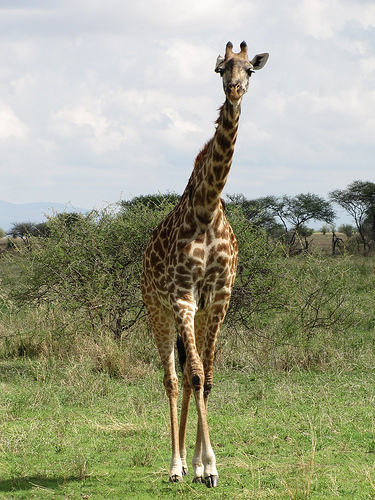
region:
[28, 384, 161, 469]
Tall grass beneath the giraffe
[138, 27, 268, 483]
A very tall giraffe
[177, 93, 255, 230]
The giraffe's neck is long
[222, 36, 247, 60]
The giraffe's antlers are small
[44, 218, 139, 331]
Small trees behind the giraffe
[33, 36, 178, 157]
Thick white clouds in the sky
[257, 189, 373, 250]
Sparse trees in the distance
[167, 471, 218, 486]
A set of black hooves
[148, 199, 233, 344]
The giraffe has many spots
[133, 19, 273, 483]
A yellow and brown giraffe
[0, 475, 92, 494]
the shadow on the ground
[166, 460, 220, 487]
the feet of the giraffe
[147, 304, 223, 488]
the giraffe's legs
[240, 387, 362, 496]
the grass on the ground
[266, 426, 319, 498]
the tall brown weeds on the grass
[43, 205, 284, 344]
the tree directly behind the giraffe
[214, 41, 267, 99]
the giraffe's head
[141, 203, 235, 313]
the body of the giraffe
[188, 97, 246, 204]
the neck of the giraffe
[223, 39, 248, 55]
the horns on the giraffe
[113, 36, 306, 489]
giraffe standing up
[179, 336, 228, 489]
one leg crossed in front of the other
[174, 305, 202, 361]
brown spots on the leg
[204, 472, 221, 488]
dark brown hoof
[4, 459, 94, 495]
shadow on the grass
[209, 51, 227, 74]
ear folded back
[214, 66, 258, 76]
two black eyes that are on opposite sides of the head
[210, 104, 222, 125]
tufts of hair sticking off the neck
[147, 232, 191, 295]
dark brown spots on the skin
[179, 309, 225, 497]
long, skinny leg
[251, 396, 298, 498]
the grass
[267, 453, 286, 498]
the grass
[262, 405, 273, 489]
the grass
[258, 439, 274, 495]
the grass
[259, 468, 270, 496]
the grass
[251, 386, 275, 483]
the grass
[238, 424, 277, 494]
the grass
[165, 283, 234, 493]
two long crossed forelegs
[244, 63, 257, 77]
giraffe's dark left eye, w/ eyelashes so long they almost look false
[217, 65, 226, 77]
giraffe's dark right eye, in shadow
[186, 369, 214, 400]
a pair of dark, rough fore-knees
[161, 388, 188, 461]
two thin, crossed hind shins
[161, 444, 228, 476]
all built-in socks are a creamy off-white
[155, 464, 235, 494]
all hooves are a silvery grey, but some are more visible than others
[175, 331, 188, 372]
long fuzzy tail of giraffe can be seen if you look hard enough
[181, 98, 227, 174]
brushy mane is blowin in the wind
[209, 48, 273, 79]
one ear goes backward, one perpendicular to contemplative face